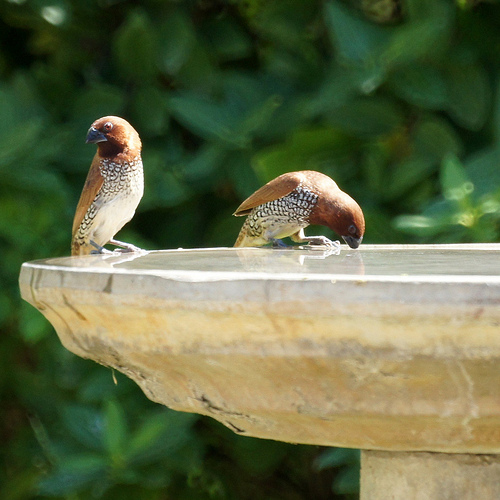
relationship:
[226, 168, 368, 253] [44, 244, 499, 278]
bird drinking water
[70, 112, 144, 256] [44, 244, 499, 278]
bird drinking water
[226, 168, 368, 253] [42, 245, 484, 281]
bird drinking water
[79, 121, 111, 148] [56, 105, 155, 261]
beak belonging to bird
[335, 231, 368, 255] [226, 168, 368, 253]
beak belonging to bird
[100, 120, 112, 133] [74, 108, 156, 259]
eye belonging to birds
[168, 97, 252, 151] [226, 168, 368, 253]
leaf growing behind bird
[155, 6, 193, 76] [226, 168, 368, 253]
leaf growing behind bird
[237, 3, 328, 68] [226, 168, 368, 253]
leaf growing behind bird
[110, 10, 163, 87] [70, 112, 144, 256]
leaf growing behind bird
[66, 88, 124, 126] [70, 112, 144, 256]
leaf growing behind bird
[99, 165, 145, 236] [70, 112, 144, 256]
breast belonging to bird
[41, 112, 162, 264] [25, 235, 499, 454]
bird sitting on bird bath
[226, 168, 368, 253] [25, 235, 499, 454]
bird sitting on bird bath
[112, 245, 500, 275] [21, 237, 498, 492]
water running off bird bath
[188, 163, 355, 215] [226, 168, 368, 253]
wing belonging to bird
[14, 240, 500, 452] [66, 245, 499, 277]
birdbath filled with water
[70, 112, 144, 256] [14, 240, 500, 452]
bird sitting on birdbath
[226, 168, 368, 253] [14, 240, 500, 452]
bird sitting on birdbath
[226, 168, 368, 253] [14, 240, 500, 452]
bird drinking from birdbath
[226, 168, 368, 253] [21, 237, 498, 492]
bird drinking from bird bath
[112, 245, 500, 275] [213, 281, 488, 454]
water in birdbath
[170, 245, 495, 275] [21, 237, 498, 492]
water in bird bath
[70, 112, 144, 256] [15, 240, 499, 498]
bird sitting on birdbath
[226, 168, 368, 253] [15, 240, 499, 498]
bird sitting on birdbath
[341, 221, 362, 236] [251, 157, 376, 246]
eye of bird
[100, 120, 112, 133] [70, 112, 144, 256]
eye of bird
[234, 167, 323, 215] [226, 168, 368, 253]
wing on bird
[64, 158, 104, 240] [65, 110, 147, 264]
wing on bird